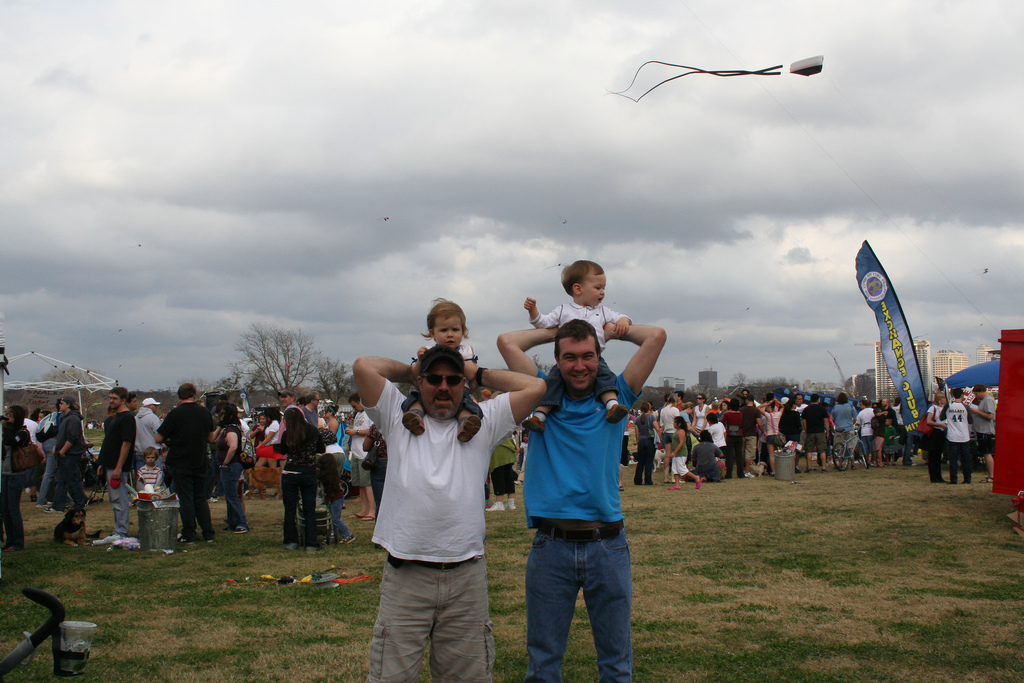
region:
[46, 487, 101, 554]
Dog laying on the ground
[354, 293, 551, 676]
Man with sunglasses holding child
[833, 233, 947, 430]
Blue and yellow flag waving in the wind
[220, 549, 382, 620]
Kite laying on the ground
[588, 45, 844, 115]
Blue and white kite flying through the sky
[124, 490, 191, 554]
Silver garbage can near dog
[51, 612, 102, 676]
Cup holder holding drink in foreground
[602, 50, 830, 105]
Kite flying in the sky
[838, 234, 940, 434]
Flag waving in the wind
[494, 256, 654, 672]
Man with blue shirt holding child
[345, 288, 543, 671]
Man with white shirt holding child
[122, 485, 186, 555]
Silver garbage can in background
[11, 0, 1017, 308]
Cloudy skies in the background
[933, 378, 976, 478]
Man with Jersey #44 in background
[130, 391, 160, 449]
Man with grey sweatshirt and white cap in background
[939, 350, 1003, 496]
a blue tent is erected in the park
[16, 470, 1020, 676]
the turf is brown with scattered green areas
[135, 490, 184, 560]
the trash can is short and silver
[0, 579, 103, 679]
the handle of a bike has a cup holder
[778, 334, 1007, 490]
tall buildings are behind the park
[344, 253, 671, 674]
two men have babies on their shoulders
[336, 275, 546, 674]
a kid over the shoulder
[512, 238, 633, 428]
kid is color white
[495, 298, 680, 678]
man has blue shirt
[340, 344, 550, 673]
man has white shirt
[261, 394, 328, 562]
woman wears blue clothes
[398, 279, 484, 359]
the baby is blond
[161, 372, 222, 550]
man wears black clothes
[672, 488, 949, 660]
patch of grass on the ground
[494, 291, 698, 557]
a person on the field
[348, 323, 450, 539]
a person on the field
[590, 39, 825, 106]
a kite in the sky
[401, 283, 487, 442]
a person is sitting down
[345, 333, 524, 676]
a person is standing up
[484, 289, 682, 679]
a person is standing up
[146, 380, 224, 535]
a person is standing up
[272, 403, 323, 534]
a person is standing up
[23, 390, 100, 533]
a person is standing up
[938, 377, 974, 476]
a person is standing up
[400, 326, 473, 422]
the head of a man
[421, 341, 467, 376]
the hat of a man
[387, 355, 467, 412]
the face of a man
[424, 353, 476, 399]
the glasses of a man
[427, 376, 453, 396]
the nose of a man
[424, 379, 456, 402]
the mustache of a man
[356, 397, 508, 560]
the white shirt of a man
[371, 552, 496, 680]
the pants of a man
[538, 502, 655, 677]
the jeans of a man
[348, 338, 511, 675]
person standing at the festival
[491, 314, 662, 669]
person standing at the festival